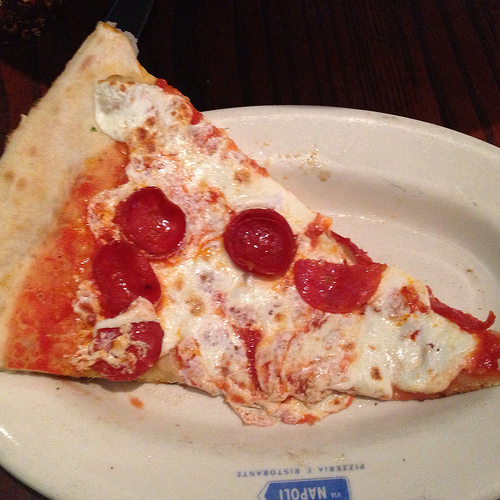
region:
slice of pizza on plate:
[2, 15, 498, 407]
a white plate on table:
[10, 58, 494, 495]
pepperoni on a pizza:
[215, 202, 302, 279]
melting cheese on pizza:
[245, 329, 447, 413]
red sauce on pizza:
[57, 268, 163, 378]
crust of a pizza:
[33, 41, 180, 139]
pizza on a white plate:
[4, 28, 498, 460]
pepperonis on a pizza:
[89, 172, 380, 342]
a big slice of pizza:
[4, 25, 497, 442]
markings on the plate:
[230, 450, 359, 498]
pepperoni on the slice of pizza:
[220, 205, 296, 279]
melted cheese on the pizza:
[139, 109, 201, 191]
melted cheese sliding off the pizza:
[231, 383, 321, 431]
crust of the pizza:
[7, 92, 76, 202]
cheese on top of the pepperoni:
[105, 303, 153, 363]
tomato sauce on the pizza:
[479, 340, 496, 373]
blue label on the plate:
[222, 453, 353, 498]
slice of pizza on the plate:
[57, 70, 495, 413]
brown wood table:
[208, 35, 424, 100]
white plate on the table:
[274, 48, 479, 208]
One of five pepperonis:
[220, 205, 297, 280]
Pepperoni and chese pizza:
[4, 23, 498, 398]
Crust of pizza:
[0, 9, 185, 370]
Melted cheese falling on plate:
[195, 389, 365, 427]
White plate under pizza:
[7, 96, 497, 498]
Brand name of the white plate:
[224, 456, 384, 498]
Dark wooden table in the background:
[10, 3, 494, 133]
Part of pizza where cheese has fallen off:
[8, 262, 105, 359]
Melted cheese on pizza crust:
[82, 72, 184, 143]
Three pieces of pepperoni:
[84, 178, 184, 390]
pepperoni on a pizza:
[200, 191, 401, 339]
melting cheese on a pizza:
[170, 306, 358, 430]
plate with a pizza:
[6, 71, 493, 498]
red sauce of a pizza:
[32, 242, 177, 383]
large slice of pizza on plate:
[5, 48, 482, 494]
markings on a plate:
[224, 440, 373, 497]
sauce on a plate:
[127, 395, 147, 410]